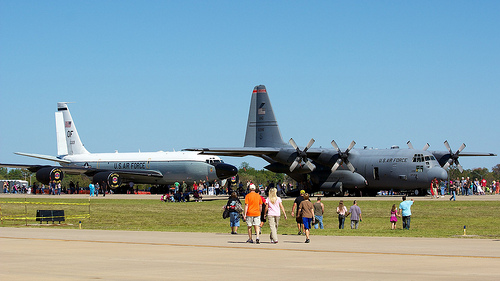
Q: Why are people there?
A: Viewing planes.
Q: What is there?
A: Airplanes.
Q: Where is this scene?
A: Airfield.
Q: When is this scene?
A: Afternoon.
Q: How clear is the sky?
A: Very clear.